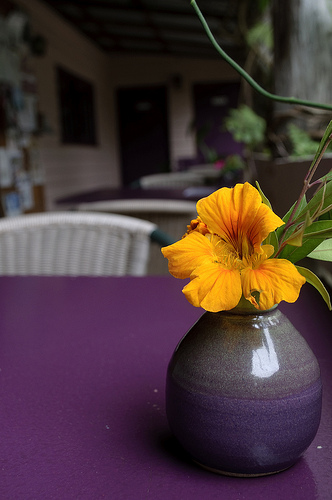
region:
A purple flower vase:
[157, 294, 327, 487]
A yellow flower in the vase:
[161, 197, 305, 316]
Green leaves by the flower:
[242, 174, 320, 282]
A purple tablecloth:
[12, 307, 91, 460]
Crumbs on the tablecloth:
[139, 374, 163, 414]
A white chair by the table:
[0, 211, 151, 276]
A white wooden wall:
[50, 154, 110, 190]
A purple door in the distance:
[201, 81, 253, 157]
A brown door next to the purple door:
[119, 82, 175, 186]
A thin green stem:
[187, 7, 325, 122]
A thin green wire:
[193, 24, 331, 127]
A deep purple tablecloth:
[14, 293, 105, 376]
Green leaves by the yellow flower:
[249, 192, 328, 289]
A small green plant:
[223, 101, 269, 146]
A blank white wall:
[55, 151, 118, 194]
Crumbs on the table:
[135, 369, 163, 420]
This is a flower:
[150, 174, 316, 319]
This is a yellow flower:
[154, 166, 310, 316]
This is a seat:
[0, 200, 197, 276]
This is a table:
[1, 267, 324, 499]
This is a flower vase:
[160, 190, 330, 481]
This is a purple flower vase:
[147, 180, 329, 489]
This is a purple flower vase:
[1, 265, 329, 490]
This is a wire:
[186, 0, 330, 125]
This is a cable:
[191, 1, 328, 105]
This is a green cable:
[191, 2, 330, 123]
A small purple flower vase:
[162, 295, 325, 476]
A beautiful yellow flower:
[161, 183, 297, 314]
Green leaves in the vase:
[249, 194, 327, 293]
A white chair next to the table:
[0, 205, 159, 277]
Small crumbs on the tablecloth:
[109, 379, 168, 438]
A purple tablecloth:
[5, 300, 110, 386]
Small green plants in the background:
[227, 98, 273, 146]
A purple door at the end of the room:
[195, 84, 249, 154]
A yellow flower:
[161, 181, 290, 309]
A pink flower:
[213, 156, 228, 172]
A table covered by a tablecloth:
[1, 273, 331, 497]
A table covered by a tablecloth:
[58, 185, 222, 202]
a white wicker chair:
[0, 210, 175, 279]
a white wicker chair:
[79, 198, 198, 275]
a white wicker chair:
[141, 171, 204, 185]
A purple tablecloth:
[2, 274, 331, 498]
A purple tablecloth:
[57, 186, 213, 203]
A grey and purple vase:
[166, 292, 322, 477]